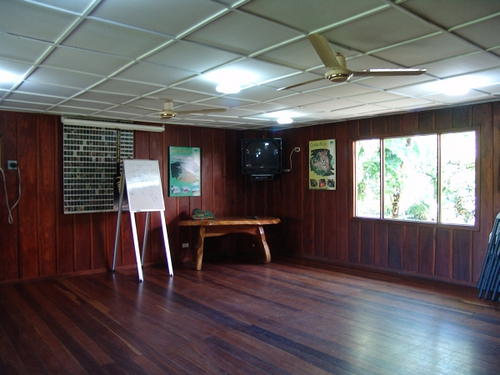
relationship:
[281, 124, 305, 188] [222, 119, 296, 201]
wire on tv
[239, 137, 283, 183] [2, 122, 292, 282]
television mounted on wall wall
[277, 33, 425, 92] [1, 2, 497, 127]
ceiling fan hanging from ceiling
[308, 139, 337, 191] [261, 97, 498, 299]
painting on wall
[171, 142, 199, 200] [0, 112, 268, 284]
art frame hanging on wall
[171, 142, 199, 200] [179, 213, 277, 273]
art frame hanging above table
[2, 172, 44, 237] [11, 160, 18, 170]
wire plugged into socket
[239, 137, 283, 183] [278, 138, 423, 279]
television on wall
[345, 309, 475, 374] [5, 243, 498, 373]
reflection on floor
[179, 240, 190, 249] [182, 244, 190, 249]
plug in plug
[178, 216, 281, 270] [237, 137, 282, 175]
table under tv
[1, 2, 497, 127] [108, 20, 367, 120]
ceiling with design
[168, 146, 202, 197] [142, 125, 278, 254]
art frame on wall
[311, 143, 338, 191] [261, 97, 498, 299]
painting on wall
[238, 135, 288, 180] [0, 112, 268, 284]
television on wall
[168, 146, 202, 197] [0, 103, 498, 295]
art frame on wall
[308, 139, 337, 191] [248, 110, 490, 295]
painting on wall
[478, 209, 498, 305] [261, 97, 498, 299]
chairs on wall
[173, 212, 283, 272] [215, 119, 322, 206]
table below television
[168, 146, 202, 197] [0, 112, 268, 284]
art frame on wall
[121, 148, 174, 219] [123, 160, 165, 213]
board attached to board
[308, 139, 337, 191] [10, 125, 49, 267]
painting on wall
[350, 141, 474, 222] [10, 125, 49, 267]
window in wall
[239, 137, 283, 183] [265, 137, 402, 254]
television on wall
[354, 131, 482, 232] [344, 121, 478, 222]
window on window